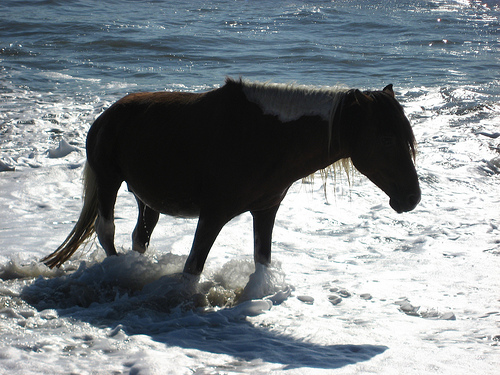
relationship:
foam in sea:
[37, 67, 70, 76] [22, 99, 54, 113]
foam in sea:
[37, 67, 103, 89] [8, 99, 54, 115]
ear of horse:
[351, 86, 376, 111] [89, 103, 368, 333]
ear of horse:
[351, 86, 376, 111] [44, 55, 436, 340]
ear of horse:
[373, 81, 403, 110] [106, 100, 295, 220]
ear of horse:
[370, 99, 387, 110] [44, 55, 436, 340]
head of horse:
[343, 82, 423, 214] [117, 115, 287, 271]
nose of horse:
[402, 175, 429, 212] [83, 155, 273, 255]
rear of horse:
[48, 84, 160, 240] [60, 139, 308, 319]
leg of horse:
[171, 258, 208, 333] [85, 116, 326, 204]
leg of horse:
[258, 228, 278, 293] [86, 120, 369, 233]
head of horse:
[366, 114, 434, 231] [54, 65, 431, 320]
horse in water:
[45, 67, 439, 306] [49, 253, 348, 367]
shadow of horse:
[84, 260, 386, 375] [114, 104, 314, 189]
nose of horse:
[402, 181, 422, 213] [44, 55, 436, 340]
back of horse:
[102, 75, 374, 111] [64, 134, 408, 198]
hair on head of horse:
[285, 72, 378, 112] [50, 108, 441, 329]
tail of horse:
[62, 172, 110, 283] [16, 55, 429, 313]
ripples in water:
[48, 52, 336, 71] [19, 99, 60, 138]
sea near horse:
[0, 0, 500, 373] [72, 100, 395, 304]